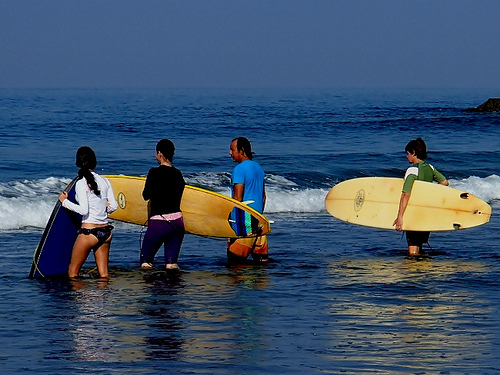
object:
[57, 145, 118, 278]
woman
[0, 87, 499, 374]
water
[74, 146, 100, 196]
hair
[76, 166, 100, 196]
ponytail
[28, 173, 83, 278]
surfboard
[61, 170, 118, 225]
shirt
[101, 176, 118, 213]
sleeve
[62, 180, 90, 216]
sleeve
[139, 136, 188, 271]
woman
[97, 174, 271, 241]
surfboard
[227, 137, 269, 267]
man